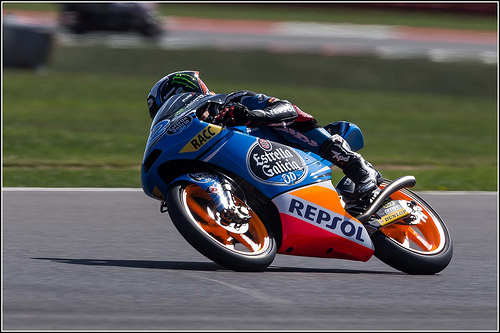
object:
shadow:
[30, 257, 216, 271]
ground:
[0, 275, 498, 333]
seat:
[323, 121, 365, 152]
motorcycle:
[139, 92, 453, 275]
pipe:
[355, 175, 416, 222]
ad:
[286, 199, 365, 242]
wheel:
[364, 178, 454, 276]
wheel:
[164, 170, 277, 271]